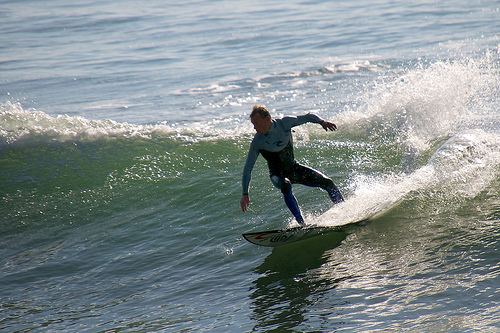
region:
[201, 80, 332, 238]
man is on surfboard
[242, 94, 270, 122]
man has brown hair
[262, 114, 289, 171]
blue and black top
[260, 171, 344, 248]
man has black wetsuit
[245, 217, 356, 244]
man on white surfboard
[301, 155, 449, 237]
man makes wake in water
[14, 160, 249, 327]
water is light blue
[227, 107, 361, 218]
man has arms extended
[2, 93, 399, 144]
white wave behind man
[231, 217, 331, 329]
man makes reflection in water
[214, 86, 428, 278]
a man is surfing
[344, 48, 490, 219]
water is splashing behind the man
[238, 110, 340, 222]
the man is wearing a wet suit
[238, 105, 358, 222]
the mans wet suit is blue and black in color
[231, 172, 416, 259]
the man is on a surfboard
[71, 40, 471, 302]
the man is surrounded by water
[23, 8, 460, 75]
the water is blue in color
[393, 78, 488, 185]
the splashing water appears white in color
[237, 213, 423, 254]
the board has some graphic design on the bottom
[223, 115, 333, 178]
the top portion of the wet suit is blue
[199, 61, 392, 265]
a man surfing in the water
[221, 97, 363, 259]
a man surfing in the ocean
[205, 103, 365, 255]
a man riding a surf board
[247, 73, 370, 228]
a man wearing a wet suit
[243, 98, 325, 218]
a man wearing a blue and black wetsuit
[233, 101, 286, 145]
a man with his head turned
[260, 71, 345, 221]
a man with his arm raised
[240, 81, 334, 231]
a man with is knees bent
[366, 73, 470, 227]
a white wave in the water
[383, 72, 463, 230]
a white wave in the ocean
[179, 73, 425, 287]
a person on a surfboard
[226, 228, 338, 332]
a reflection of a surfboard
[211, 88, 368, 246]
a white and black wetsuit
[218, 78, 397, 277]
a man and board in water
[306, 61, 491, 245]
white water spraying in the air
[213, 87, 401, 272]
a man in a wetsuit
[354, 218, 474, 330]
light reflected on the water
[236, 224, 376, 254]
a white board with black on it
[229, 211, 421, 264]
a surfboard in the water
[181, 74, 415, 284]
a man surfing on a wave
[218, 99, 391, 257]
male surfer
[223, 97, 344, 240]
mlae surfer in black wet suit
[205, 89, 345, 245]
surfer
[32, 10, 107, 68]
white and blue ocean waves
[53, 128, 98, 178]
white and blue ocean waves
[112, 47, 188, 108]
white and blue ocean waves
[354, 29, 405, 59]
white and blue ocean waves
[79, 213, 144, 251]
white and blue ocean waves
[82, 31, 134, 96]
white and blue ocean waves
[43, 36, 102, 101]
white and blue ocean waves